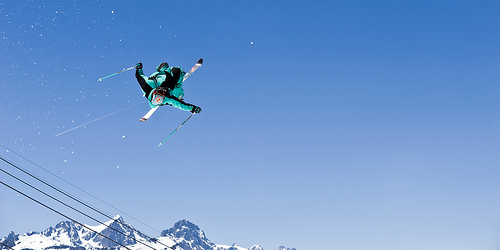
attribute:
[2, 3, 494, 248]
sky — blue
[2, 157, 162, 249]
power lines — black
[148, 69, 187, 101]
snow suit — light blue and black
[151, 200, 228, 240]
mountains — rocky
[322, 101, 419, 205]
sky — clear, blue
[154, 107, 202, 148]
pole — thin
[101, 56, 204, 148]
skier — upside down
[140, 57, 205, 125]
ski — white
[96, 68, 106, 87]
flecks — small, snow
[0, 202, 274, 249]
mountains — snow covered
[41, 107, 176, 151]
power poles — black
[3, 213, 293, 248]
mountains — jagged, snow covered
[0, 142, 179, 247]
cables — black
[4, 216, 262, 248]
mountain range — large